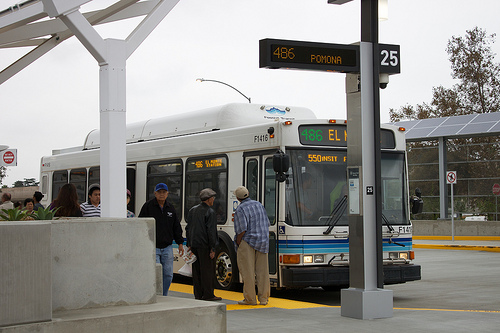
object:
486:
[272, 46, 295, 58]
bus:
[38, 102, 423, 293]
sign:
[447, 171, 457, 184]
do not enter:
[447, 172, 455, 182]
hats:
[200, 188, 217, 198]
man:
[232, 183, 271, 306]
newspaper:
[176, 243, 198, 265]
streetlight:
[189, 76, 252, 105]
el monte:
[327, 127, 347, 142]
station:
[0, 22, 401, 333]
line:
[168, 282, 324, 309]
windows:
[185, 157, 225, 224]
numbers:
[380, 50, 397, 65]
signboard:
[379, 45, 400, 74]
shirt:
[234, 198, 270, 253]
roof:
[0, 0, 134, 82]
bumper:
[285, 264, 420, 288]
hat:
[154, 182, 168, 193]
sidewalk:
[166, 281, 496, 332]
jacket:
[138, 198, 186, 249]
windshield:
[288, 152, 406, 227]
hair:
[52, 183, 80, 222]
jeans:
[148, 245, 175, 296]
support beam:
[99, 33, 128, 215]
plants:
[27, 207, 60, 220]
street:
[397, 246, 500, 304]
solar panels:
[402, 113, 498, 138]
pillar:
[63, 11, 162, 217]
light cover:
[268, 127, 275, 135]